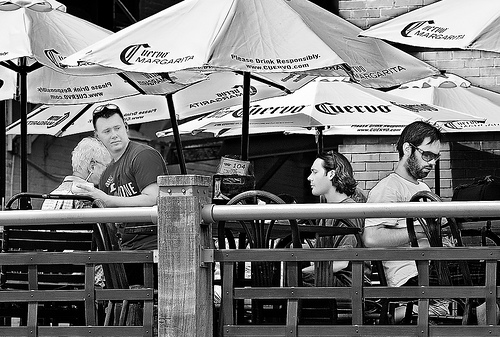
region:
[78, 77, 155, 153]
head of a person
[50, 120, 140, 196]
head of a person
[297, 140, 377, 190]
head of a person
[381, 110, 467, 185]
head of a person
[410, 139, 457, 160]
eye of a person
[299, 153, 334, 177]
eye of a person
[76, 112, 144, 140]
eye of a person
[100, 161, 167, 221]
arm of a person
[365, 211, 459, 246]
arm of a person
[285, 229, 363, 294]
arm of a person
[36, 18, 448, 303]
The photo is black and white.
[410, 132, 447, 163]
The man is wearing glasses.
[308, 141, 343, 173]
The man has sunglasses on top of head.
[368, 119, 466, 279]
The man is sitting in chair.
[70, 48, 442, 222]
People under the umbrellas.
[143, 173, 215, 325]
The pole of the railing is wood.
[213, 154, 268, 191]
A menu in the box.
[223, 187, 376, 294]
Table and chairs under the umbrella.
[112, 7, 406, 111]
The umbrella is up.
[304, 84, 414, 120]
Black writing on the umbrella.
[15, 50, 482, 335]
people sitting in chairs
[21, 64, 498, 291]
the people are on an outdoor patio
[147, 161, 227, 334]
this is a wooden post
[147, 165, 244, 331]
a wooden fence post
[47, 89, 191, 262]
he is holding a glass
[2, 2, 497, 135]
these are table umbrellas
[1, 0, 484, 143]
the umbrellas are branded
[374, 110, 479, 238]
this man is wearing sunglasses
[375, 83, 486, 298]
he has a beard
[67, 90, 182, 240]
he has earbuds in his ears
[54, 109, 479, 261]
people sitting in a cafe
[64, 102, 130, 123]
a man wearing sunglasses on his head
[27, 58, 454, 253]
people sitting under umbrellas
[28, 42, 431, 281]
umbrellla's sticking in the center of tables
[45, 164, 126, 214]
a man holding a piece of paper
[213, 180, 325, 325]
chairs sitting under the tables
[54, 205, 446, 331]
railing surrounding a seating area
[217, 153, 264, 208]
a menu sitting on top of a table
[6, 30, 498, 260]
this is black and white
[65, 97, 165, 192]
this is a man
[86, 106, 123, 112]
the man has glasses on his head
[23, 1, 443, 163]
these are umbrellas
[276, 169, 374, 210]
this man has long hair